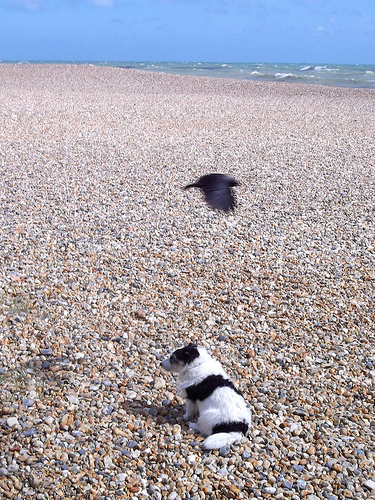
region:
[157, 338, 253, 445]
a dog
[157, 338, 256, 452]
a small dog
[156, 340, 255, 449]
the dog is black and white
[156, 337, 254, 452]
a small black and white dog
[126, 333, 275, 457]
a dog sitting in the rocks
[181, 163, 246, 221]
a black bird is flying by the dog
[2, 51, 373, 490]
a beach full of pebbles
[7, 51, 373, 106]
the ocean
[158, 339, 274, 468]
the dog is not looking at the bird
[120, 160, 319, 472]
a black bird flying over the small dog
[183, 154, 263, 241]
a bird in flight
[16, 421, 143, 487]
a variety of pebbles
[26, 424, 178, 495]
a pile of rocks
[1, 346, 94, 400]
a shadow of a bird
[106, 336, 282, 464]
a dog on a rocky beach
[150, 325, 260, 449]
a black and white dog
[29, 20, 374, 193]
a rocky ocean shore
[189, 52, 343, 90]
a few small waves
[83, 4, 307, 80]
a blue sky over the ocean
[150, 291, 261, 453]
a dog sitting down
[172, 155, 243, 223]
One bird is flying.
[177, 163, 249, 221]
the bird is black.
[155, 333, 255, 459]
One dog at the beach.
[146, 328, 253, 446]
the dog is sitting on rocks.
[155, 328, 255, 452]
the dog is black and white.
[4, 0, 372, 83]
the sky is blue.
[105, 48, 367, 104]
the water is blue.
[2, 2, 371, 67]
the sky is clear.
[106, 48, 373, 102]
the water is choppy.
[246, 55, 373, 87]
the waves are white.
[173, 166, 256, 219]
the bird is black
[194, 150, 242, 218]
the wing on bird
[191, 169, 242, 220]
the bird is blurry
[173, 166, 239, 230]
the bird is flying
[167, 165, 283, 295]
bird above the rocks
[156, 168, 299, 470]
bird above the dog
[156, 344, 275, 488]
the dog is in the rocks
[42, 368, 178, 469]
the rocks are colorful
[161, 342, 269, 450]
dog is black and white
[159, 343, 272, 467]
the dog is sitting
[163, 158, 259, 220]
Black bird in mid flight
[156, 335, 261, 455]
Black and white dog sitting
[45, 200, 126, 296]
Ground covered in small rocks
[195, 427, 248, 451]
Dog's all white tail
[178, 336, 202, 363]
Dog has black ears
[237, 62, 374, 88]
Waves close to shore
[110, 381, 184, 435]
Shadow of dog on rocks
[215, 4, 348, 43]
Group of clouds in sky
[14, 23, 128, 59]
Bright blue sky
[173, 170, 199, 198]
Black tail on bird